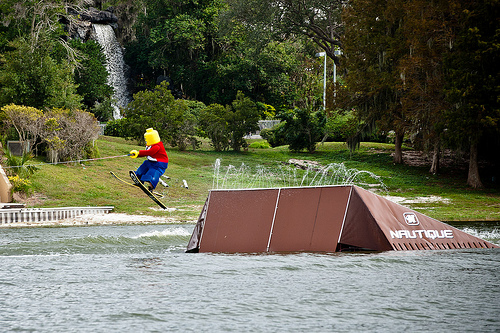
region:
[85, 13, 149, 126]
waterfall in the background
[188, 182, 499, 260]
brown water ski ramp in water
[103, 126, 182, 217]
skier dressed as lego toy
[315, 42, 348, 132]
tall lamp posts in background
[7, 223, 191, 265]
wake left by boat in water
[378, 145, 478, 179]
rock wall behind trees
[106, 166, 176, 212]
black skies on skier's feet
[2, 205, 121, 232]
concrete wall on shore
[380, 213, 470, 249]
the word Nautique on ski ramp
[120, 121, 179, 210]
skier wearing blue costume pants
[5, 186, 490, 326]
brown ramp over gray rippling water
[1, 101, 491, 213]
trees and bushes on gently sloped lawn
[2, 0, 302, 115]
waterfall between dense trees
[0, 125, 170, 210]
person in air while water skiing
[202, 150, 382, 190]
individual sprays of water curving in air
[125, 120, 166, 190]
waterskier wearing yellow bucket over head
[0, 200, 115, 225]
low white railing at edge of water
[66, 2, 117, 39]
large gray rocks on top of waterfall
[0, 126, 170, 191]
waterskier in red and blue outfit holding taut rope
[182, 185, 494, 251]
name and logo on fabric covering ramp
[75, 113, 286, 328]
this is a man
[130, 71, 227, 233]
this is a lego suit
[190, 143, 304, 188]
this is a sprinkler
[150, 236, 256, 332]
this is some water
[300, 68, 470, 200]
these are old trees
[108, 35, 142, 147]
this is a waterfall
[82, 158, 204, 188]
the shorts are blue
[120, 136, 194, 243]
this is a water ski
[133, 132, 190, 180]
this is a shirt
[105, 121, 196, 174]
the shirt is red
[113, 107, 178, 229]
a person wearing a costume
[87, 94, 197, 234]
a person jumping a ramp on water skis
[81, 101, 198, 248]
a person up over the water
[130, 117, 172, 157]
a person with a yellow mask on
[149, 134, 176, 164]
a person wearing a red shirt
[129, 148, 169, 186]
a person wearing blue pants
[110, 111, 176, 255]
a person on water skis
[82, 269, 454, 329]
a body of water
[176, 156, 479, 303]
a ramp in the water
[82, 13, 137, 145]
a water fall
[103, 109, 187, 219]
lego costumed water skiier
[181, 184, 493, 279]
ski ramp in the water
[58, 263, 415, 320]
water of a lake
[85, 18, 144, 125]
waterfall at a park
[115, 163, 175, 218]
water skiis on lego character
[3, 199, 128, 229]
white fence by the water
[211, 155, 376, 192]
water sprinkling above the ramp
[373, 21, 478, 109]
green leaves on trees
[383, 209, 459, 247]
advertisement on a ramp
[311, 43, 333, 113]
lights on a pole